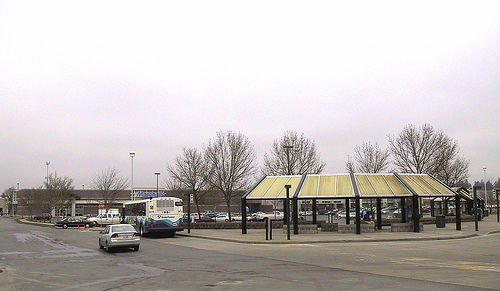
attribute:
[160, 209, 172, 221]
logo — blue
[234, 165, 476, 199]
stand — yellow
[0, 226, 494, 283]
road — dark grey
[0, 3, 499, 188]
sky — heavy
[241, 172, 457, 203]
roof — gold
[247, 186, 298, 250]
stand — yellow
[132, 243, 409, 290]
sidewalk — dark grey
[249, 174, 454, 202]
roof — gold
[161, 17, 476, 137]
sky — dark, cloudy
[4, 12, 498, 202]
sky — grey, cloudy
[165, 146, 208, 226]
tree — tall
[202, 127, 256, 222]
tree — tall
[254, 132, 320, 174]
tree — tall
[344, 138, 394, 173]
tree — tall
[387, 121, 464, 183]
tree — tall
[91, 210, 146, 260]
car — grey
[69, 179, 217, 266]
poles — tall, white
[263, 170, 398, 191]
stand — yellow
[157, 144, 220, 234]
tree — bare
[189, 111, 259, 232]
tree — bare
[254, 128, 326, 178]
tree — bare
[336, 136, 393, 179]
tree — bare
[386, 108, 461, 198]
tree — bare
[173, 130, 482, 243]
trees — tall, bare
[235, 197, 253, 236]
pole — black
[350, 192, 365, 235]
pole — black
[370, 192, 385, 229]
pole — black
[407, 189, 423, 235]
pole — black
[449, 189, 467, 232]
pole — black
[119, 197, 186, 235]
bus — blue, white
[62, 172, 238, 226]
building — grey, blue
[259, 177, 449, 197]
stand — yellow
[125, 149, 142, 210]
light post — tall, white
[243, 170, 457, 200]
stand — yellow